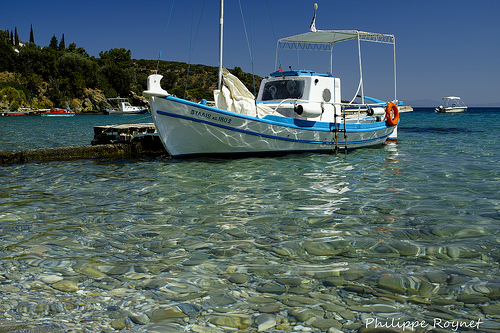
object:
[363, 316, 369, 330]
text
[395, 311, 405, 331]
text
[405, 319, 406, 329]
text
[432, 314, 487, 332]
text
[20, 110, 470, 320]
lake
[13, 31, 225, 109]
hill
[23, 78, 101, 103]
shrubs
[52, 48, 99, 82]
trees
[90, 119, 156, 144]
deck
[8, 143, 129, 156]
metal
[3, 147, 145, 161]
moss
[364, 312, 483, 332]
person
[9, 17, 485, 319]
picture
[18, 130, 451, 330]
water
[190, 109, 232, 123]
name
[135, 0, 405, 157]
boat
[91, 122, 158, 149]
dock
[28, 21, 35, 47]
trees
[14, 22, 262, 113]
background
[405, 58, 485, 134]
background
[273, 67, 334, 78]
trim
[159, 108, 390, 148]
trim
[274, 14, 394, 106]
canopy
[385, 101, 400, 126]
life preserver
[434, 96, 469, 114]
boat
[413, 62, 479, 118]
distance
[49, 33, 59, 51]
trees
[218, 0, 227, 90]
mast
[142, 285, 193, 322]
rocks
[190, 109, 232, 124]
words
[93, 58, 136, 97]
trees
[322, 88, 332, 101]
window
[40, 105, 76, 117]
boat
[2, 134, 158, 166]
pier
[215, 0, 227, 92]
pole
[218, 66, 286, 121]
tarp